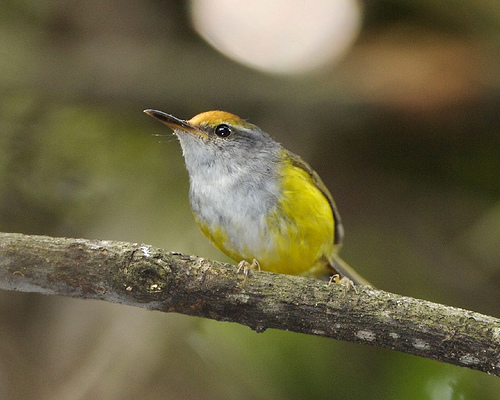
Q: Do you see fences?
A: No, there are no fences.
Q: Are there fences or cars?
A: No, there are no fences or cars.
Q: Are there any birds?
A: Yes, there is a bird.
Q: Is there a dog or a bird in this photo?
A: Yes, there is a bird.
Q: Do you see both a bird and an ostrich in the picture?
A: No, there is a bird but no ostriches.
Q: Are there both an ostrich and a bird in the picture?
A: No, there is a bird but no ostriches.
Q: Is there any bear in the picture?
A: No, there are no bears.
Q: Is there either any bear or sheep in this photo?
A: No, there are no bears or sheep.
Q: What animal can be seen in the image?
A: The animal is a bird.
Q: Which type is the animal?
A: The animal is a bird.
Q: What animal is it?
A: The animal is a bird.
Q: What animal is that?
A: This is a bird.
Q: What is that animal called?
A: This is a bird.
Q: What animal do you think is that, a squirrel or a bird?
A: This is a bird.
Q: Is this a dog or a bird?
A: This is a bird.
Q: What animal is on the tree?
A: The bird is on the tree.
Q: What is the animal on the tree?
A: The animal is a bird.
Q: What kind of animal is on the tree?
A: The animal is a bird.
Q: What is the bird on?
A: The bird is on the tree.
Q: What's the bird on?
A: The bird is on the tree.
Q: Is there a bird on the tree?
A: Yes, there is a bird on the tree.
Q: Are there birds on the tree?
A: Yes, there is a bird on the tree.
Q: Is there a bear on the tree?
A: No, there is a bird on the tree.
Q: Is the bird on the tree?
A: Yes, the bird is on the tree.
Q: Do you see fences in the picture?
A: No, there are no fences.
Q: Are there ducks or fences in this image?
A: No, there are no fences or ducks.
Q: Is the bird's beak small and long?
A: Yes, the beak is small and long.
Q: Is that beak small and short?
A: No, the beak is small but long.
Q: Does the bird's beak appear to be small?
A: Yes, the beak is small.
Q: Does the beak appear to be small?
A: Yes, the beak is small.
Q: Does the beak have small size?
A: Yes, the beak is small.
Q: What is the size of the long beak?
A: The beak is small.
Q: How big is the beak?
A: The beak is small.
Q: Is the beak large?
A: No, the beak is small.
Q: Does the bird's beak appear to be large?
A: No, the beak is small.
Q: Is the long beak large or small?
A: The beak is small.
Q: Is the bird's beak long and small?
A: Yes, the beak is long and small.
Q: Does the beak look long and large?
A: No, the beak is long but small.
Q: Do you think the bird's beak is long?
A: Yes, the beak is long.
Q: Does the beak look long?
A: Yes, the beak is long.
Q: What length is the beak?
A: The beak is long.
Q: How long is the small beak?
A: The beak is long.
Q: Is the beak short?
A: No, the beak is long.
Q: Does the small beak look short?
A: No, the beak is long.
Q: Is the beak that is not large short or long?
A: The beak is long.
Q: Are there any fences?
A: No, there are no fences.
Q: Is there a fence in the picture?
A: No, there are no fences.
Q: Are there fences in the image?
A: No, there are no fences.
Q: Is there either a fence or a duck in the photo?
A: No, there are no fences or ducks.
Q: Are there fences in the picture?
A: No, there are no fences.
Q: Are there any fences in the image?
A: No, there are no fences.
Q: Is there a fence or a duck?
A: No, there are no fences or ducks.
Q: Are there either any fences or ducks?
A: No, there are no fences or ducks.